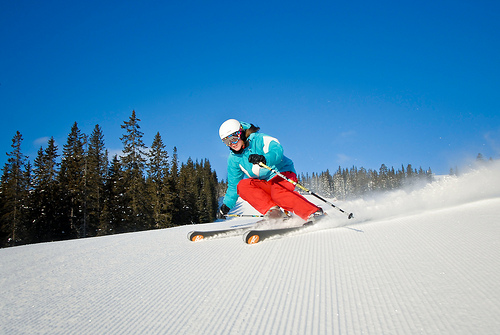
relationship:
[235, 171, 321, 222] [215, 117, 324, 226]
pants on girl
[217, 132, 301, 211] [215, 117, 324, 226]
coat on girl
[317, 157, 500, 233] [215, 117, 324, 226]
snow behind girl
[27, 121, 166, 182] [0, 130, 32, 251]
clouds behind evergreen trees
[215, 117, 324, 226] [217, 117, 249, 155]
girl has a head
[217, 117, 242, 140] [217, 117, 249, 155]
helmet on head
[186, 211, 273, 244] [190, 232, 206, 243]
ski has a circle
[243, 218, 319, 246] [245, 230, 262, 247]
ski has a circle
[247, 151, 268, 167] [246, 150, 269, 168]
glove on hand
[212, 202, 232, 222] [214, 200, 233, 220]
glove on hand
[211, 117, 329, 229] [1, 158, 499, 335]
girl skiing down hill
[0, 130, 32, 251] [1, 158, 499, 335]
evergreen trees on a hill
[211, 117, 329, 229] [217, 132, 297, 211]
girl wearing a coat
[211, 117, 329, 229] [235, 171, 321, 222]
girl wearing pants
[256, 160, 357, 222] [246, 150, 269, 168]
ski pole in hand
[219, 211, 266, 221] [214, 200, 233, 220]
ski pole in hand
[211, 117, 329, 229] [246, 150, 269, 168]
girl has hand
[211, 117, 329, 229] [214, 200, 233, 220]
girl has hand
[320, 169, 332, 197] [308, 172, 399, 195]
pine trees have snow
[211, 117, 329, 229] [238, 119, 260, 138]
girl has hair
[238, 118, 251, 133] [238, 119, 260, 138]
hair tie in hair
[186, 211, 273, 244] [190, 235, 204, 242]
ski has circle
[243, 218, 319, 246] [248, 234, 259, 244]
ski has circle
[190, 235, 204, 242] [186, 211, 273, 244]
circle underneath ski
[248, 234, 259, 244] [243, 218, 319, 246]
circle underneath ski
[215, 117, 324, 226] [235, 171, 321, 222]
girl wearing pants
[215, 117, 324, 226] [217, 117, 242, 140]
girl wearing helmet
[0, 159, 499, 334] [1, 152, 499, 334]
snow on hill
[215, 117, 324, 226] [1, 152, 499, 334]
girl skiing down hill